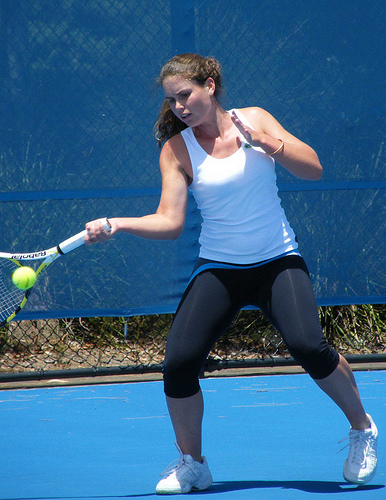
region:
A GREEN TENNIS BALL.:
[13, 266, 34, 285]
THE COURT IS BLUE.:
[36, 397, 97, 457]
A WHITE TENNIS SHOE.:
[144, 434, 217, 495]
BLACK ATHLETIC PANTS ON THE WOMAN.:
[141, 238, 351, 394]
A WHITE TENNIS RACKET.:
[9, 213, 107, 345]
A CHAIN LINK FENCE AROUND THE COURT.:
[66, 20, 160, 129]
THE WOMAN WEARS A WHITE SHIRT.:
[167, 122, 303, 279]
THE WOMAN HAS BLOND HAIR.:
[126, 53, 245, 146]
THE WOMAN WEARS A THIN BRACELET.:
[262, 134, 293, 159]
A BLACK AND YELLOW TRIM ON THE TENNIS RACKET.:
[7, 289, 30, 324]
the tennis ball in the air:
[12, 266, 37, 290]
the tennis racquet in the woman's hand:
[0, 215, 111, 326]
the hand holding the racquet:
[84, 216, 117, 246]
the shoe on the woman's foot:
[154, 441, 212, 494]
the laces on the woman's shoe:
[158, 440, 187, 479]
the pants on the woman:
[162, 247, 339, 398]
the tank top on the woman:
[179, 107, 297, 263]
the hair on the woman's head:
[150, 52, 221, 150]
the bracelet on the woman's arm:
[265, 138, 283, 156]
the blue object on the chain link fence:
[0, 1, 385, 318]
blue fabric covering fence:
[0, 2, 384, 321]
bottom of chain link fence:
[1, 303, 384, 380]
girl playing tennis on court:
[0, 51, 378, 495]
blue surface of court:
[4, 369, 384, 497]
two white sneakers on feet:
[156, 414, 376, 493]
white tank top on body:
[180, 108, 296, 263]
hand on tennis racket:
[0, 216, 115, 326]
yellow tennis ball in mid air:
[12, 267, 37, 290]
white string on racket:
[0, 257, 20, 312]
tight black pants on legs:
[161, 251, 341, 396]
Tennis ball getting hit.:
[12, 264, 37, 287]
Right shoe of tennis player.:
[154, 451, 214, 493]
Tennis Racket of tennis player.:
[0, 216, 111, 331]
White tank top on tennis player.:
[179, 106, 299, 265]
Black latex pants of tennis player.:
[159, 251, 339, 399]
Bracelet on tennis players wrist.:
[266, 137, 283, 158]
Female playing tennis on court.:
[84, 53, 377, 491]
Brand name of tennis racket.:
[8, 248, 46, 259]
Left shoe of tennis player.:
[342, 411, 377, 485]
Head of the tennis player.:
[158, 51, 218, 128]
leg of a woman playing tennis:
[133, 274, 242, 498]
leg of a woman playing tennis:
[257, 259, 384, 487]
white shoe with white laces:
[148, 436, 214, 498]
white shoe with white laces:
[336, 408, 381, 485]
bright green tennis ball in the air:
[8, 262, 40, 292]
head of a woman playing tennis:
[136, 50, 229, 152]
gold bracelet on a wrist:
[259, 135, 285, 163]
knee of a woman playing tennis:
[282, 331, 337, 369]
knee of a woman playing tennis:
[148, 341, 202, 395]